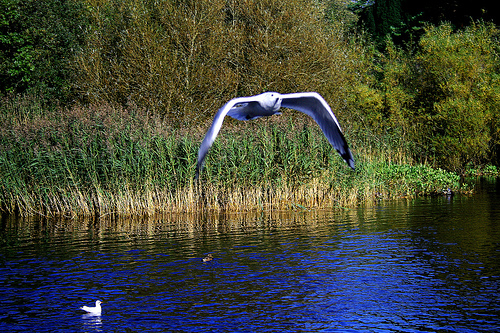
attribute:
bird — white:
[79, 297, 102, 317]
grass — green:
[63, 130, 400, 193]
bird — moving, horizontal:
[187, 82, 360, 184]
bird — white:
[74, 294, 106, 319]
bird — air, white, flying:
[192, 88, 357, 173]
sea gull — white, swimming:
[191, 92, 353, 184]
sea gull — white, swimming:
[78, 297, 104, 319]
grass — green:
[63, 132, 145, 169]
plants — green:
[2, 91, 468, 195]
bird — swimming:
[198, 74, 372, 179]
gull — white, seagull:
[181, 81, 361, 192]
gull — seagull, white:
[193, 242, 226, 274]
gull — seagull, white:
[70, 288, 124, 326]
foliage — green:
[20, 30, 215, 182]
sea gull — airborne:
[156, 54, 369, 192]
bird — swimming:
[69, 296, 109, 321]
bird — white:
[183, 79, 382, 199]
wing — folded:
[194, 87, 249, 169]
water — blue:
[254, 224, 411, 321]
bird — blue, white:
[181, 73, 376, 177]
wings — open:
[189, 114, 356, 181]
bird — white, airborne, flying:
[191, 87, 356, 181]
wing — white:
[282, 89, 358, 172]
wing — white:
[192, 92, 252, 177]